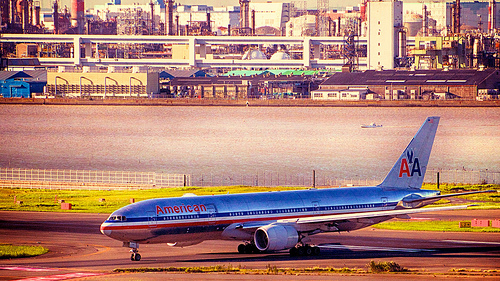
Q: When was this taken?
A: Daytime.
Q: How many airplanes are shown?
A: 1.